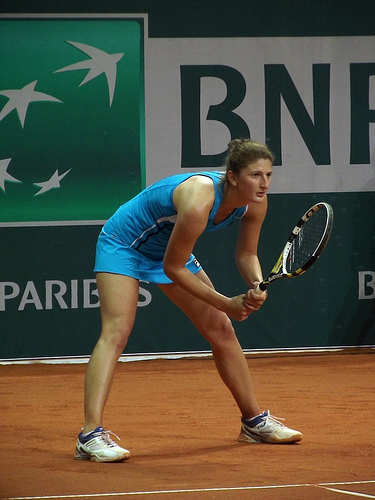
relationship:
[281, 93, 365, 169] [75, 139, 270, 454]
wall behind person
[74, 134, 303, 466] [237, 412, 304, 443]
player wearing shoe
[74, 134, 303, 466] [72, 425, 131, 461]
player wearing shoe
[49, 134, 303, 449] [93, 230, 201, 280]
player wearing blue skirt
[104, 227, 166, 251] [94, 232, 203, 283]
tag on shorts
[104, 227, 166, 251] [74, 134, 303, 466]
tag on player